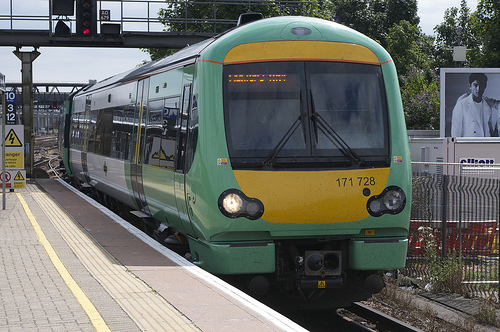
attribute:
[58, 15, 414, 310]
train — green, outdoors, aqua, yellow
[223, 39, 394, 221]
front — yellow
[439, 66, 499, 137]
ad — black, white, gray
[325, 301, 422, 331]
tracks — metal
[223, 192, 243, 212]
light — on, lit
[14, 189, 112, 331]
stripe — yellow, thin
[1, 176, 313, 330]
platform — concrete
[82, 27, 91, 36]
light — red, small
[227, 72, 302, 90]
display — orange, digital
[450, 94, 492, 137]
shirt — white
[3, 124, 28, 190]
warning sign — yellow, white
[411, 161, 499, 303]
fence — metal, small, black, short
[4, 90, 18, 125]
sign — blue, black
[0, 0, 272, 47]
crosswalk — metal, overhead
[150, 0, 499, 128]
trees — green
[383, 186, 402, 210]
light — off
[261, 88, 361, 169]
wipers — black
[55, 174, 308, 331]
curb — white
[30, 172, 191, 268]
shadow — long, black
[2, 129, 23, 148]
triangle — yellow, black